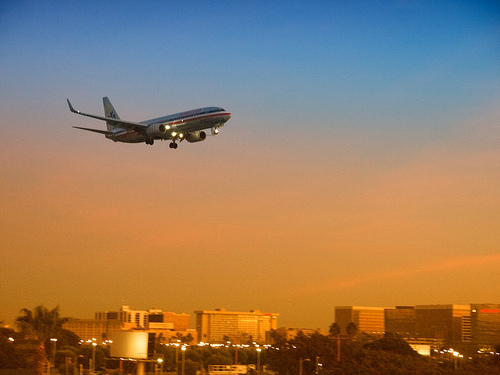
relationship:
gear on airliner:
[164, 142, 176, 150] [66, 96, 228, 148]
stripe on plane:
[161, 111, 230, 119] [56, 86, 244, 137]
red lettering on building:
[475, 307, 497, 314] [475, 315, 499, 349]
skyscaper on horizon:
[196, 297, 274, 342] [2, 313, 499, 348]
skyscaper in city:
[196, 297, 274, 342] [2, 299, 498, 374]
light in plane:
[179, 133, 184, 138] [66, 96, 231, 148]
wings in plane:
[53, 93, 173, 175] [67, 69, 241, 144]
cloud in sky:
[2, 139, 494, 319] [4, 6, 489, 302]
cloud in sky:
[2, 139, 494, 319] [0, 0, 497, 344]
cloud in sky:
[2, 139, 494, 319] [298, 112, 376, 153]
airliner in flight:
[66, 96, 228, 148] [29, 39, 424, 200]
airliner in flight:
[66, 96, 228, 148] [10, 18, 458, 205]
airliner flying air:
[66, 96, 228, 148] [5, 8, 483, 326]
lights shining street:
[33, 329, 275, 364] [4, 349, 484, 371]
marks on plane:
[109, 118, 128, 132] [45, 73, 278, 158]